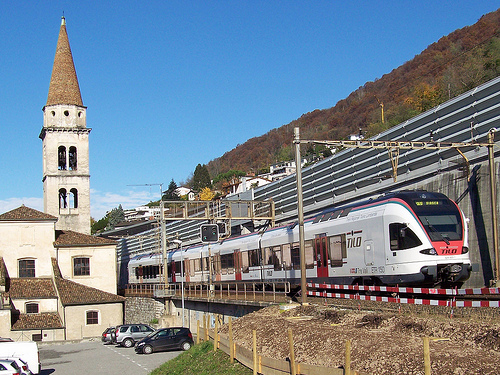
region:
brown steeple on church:
[19, 37, 95, 120]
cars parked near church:
[109, 289, 195, 369]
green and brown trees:
[241, 31, 467, 162]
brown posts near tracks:
[170, 314, 480, 374]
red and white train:
[121, 206, 441, 293]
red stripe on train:
[266, 192, 455, 254]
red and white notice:
[300, 278, 499, 297]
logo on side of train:
[335, 226, 380, 258]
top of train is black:
[387, 187, 453, 248]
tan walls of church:
[13, 229, 114, 341]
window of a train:
[408, 205, 466, 244]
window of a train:
[388, 222, 415, 247]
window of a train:
[325, 236, 351, 261]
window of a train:
[293, 239, 327, 266]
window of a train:
[270, 244, 299, 267]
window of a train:
[262, 245, 283, 272]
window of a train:
[240, 247, 256, 276]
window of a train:
[196, 253, 206, 276]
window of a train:
[185, 257, 195, 274]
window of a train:
[191, 258, 208, 273]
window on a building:
[18, 259, 36, 280]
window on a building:
[21, 302, 39, 313]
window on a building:
[31, 332, 42, 342]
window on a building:
[73, 256, 90, 279]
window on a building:
[86, 311, 99, 325]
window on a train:
[418, 213, 461, 240]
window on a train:
[388, 221, 416, 248]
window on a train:
[321, 236, 328, 268]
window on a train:
[282, 240, 292, 267]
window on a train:
[270, 246, 282, 270]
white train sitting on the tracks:
[129, 188, 471, 284]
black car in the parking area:
[134, 327, 194, 354]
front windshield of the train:
[416, 209, 466, 241]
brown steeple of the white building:
[42, 16, 86, 105]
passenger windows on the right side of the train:
[136, 233, 347, 280]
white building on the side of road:
[2, 16, 124, 340]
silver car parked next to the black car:
[115, 324, 157, 348]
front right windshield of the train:
[389, 222, 422, 250]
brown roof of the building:
[0, 205, 59, 223]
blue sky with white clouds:
[1, 0, 498, 221]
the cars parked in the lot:
[0, 323, 193, 374]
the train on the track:
[116, 188, 471, 288]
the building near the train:
[0, 8, 123, 340]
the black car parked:
[135, 326, 194, 353]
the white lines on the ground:
[96, 338, 152, 373]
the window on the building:
[72, 256, 92, 276]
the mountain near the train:
[143, 7, 498, 207]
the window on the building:
[25, 303, 38, 314]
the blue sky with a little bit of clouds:
[0, 0, 497, 222]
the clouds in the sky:
[0, 188, 167, 221]